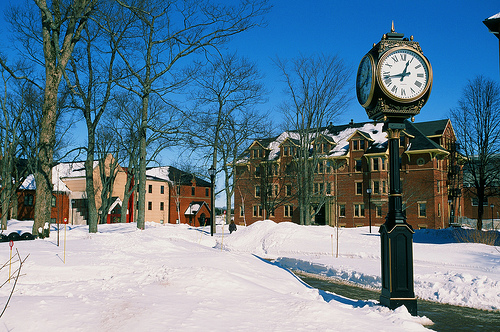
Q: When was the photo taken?
A: 12:44.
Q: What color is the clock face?
A: White.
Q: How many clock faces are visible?
A: 2.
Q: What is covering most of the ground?
A: Snow.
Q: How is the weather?
A: Clear.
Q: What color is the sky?
A: Blue.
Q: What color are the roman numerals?
A: Black.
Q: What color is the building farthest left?
A: Red.